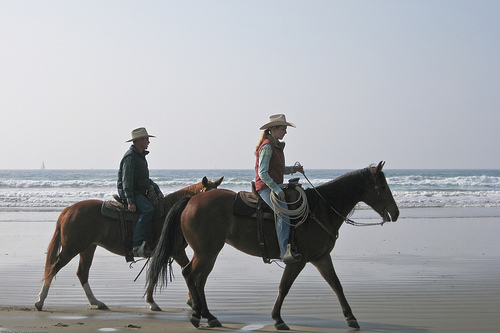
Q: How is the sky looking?
A: Blue and cloudless.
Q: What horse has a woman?
A: Taller horse.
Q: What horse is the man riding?
A: Shorter horse.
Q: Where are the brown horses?
A: On beach.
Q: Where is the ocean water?
A: Beyond sand.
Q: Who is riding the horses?
A: Two people.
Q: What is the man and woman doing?
A: Riding the horses.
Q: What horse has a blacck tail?
A: Taller horse.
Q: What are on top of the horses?
A: Two humans.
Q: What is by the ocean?
A: A beach.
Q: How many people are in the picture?
A: Two.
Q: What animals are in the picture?
A: Horses.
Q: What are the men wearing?
A: Hats.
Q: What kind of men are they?
A: Cowboys.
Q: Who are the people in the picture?
A: Men.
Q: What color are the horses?
A: Brown.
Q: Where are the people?
A: By the water.